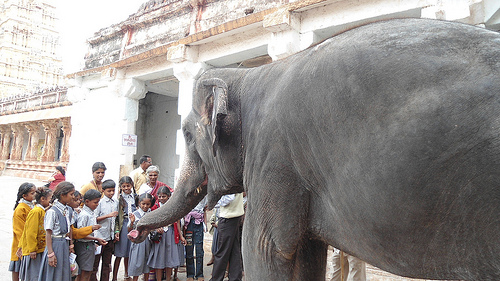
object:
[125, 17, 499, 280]
elephant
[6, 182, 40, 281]
children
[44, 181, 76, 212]
hair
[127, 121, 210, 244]
trunk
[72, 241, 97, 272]
slacks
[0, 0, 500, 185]
building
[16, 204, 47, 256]
jackets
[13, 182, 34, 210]
pigtails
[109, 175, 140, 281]
girl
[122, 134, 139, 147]
sign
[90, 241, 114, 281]
pants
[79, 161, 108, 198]
woman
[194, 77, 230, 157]
ear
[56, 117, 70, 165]
columns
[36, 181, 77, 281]
girls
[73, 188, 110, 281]
boys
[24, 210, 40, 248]
yellow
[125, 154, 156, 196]
man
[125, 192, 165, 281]
kids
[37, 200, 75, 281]
uniform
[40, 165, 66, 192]
person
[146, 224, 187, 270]
dress